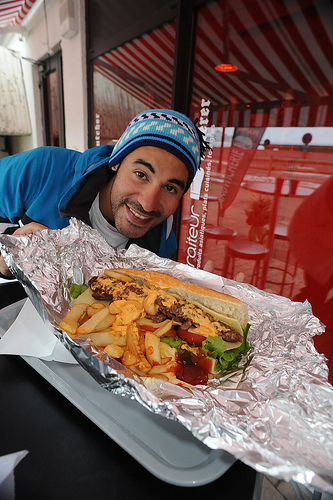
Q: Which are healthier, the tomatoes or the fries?
A: The tomatoes are healthier than the fries.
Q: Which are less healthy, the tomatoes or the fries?
A: The fries are less healthy than the tomatoes.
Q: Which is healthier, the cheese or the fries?
A: The cheese is healthier than the fries.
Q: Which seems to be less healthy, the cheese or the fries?
A: The fries is less healthy than the cheese.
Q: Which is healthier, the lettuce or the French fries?
A: The lettuce is healthier than the French fries.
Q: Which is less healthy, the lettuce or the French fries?
A: The French fries is less healthy than the lettuce.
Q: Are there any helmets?
A: No, there are no helmets.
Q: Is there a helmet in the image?
A: No, there are no helmets.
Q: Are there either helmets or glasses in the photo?
A: No, there are no helmets or glasses.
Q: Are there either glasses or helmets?
A: No, there are no helmets or glasses.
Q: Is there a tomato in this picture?
A: Yes, there are tomatoes.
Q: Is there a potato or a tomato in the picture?
A: Yes, there are tomatoes.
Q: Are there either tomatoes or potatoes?
A: Yes, there are tomatoes.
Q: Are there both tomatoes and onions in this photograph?
A: No, there are tomatoes but no onions.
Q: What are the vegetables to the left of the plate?
A: The vegetables are tomatoes.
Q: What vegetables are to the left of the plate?
A: The vegetables are tomatoes.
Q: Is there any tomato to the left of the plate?
A: Yes, there are tomatoes to the left of the plate.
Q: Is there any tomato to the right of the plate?
A: No, the tomatoes are to the left of the plate.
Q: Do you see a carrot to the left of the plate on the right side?
A: No, there are tomatoes to the left of the plate.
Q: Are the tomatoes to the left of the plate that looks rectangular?
A: Yes, the tomatoes are to the left of the plate.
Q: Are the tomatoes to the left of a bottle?
A: No, the tomatoes are to the left of the plate.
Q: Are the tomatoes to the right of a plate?
A: No, the tomatoes are to the left of a plate.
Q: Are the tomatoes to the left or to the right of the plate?
A: The tomatoes are to the left of the plate.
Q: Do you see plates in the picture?
A: Yes, there is a plate.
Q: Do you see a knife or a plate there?
A: Yes, there is a plate.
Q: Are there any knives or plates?
A: Yes, there is a plate.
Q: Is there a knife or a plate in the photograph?
A: Yes, there is a plate.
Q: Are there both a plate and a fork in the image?
A: No, there is a plate but no forks.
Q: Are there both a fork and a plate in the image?
A: No, there is a plate but no forks.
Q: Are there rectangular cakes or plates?
A: Yes, there is a rectangular plate.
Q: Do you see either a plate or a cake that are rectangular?
A: Yes, the plate is rectangular.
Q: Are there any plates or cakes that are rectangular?
A: Yes, the plate is rectangular.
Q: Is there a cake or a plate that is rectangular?
A: Yes, the plate is rectangular.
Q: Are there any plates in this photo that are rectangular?
A: Yes, there is a rectangular plate.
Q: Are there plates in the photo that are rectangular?
A: Yes, there is a plate that is rectangular.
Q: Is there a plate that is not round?
A: Yes, there is a rectangular plate.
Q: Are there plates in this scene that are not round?
A: Yes, there is a rectangular plate.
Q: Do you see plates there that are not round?
A: Yes, there is a rectangular plate.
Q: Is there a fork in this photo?
A: No, there are no forks.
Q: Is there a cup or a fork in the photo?
A: No, there are no forks or cups.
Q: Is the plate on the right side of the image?
A: Yes, the plate is on the right of the image.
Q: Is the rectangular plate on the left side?
A: No, the plate is on the right of the image.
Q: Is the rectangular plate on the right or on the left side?
A: The plate is on the right of the image.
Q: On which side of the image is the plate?
A: The plate is on the right of the image.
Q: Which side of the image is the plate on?
A: The plate is on the right of the image.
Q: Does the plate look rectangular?
A: Yes, the plate is rectangular.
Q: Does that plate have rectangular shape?
A: Yes, the plate is rectangular.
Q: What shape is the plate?
A: The plate is rectangular.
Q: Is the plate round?
A: No, the plate is rectangular.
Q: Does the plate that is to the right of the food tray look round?
A: No, the plate is rectangular.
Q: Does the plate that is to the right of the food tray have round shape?
A: No, the plate is rectangular.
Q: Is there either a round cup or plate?
A: No, there is a plate but it is rectangular.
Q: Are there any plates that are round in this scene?
A: No, there is a plate but it is rectangular.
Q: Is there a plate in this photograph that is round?
A: No, there is a plate but it is rectangular.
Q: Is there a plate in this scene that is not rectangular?
A: No, there is a plate but it is rectangular.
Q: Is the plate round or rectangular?
A: The plate is rectangular.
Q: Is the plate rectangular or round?
A: The plate is rectangular.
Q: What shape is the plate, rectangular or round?
A: The plate is rectangular.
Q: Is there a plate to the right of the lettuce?
A: Yes, there is a plate to the right of the lettuce.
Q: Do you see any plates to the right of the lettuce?
A: Yes, there is a plate to the right of the lettuce.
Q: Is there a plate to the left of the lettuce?
A: No, the plate is to the right of the lettuce.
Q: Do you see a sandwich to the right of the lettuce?
A: No, there is a plate to the right of the lettuce.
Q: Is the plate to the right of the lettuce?
A: Yes, the plate is to the right of the lettuce.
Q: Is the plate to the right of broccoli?
A: No, the plate is to the right of the lettuce.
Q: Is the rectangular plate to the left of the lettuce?
A: No, the plate is to the right of the lettuce.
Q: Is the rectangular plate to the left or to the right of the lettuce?
A: The plate is to the right of the lettuce.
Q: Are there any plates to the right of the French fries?
A: Yes, there is a plate to the right of the French fries.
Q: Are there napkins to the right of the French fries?
A: No, there is a plate to the right of the French fries.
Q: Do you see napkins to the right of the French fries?
A: No, there is a plate to the right of the French fries.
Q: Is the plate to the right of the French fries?
A: Yes, the plate is to the right of the French fries.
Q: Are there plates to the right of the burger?
A: Yes, there is a plate to the right of the burger.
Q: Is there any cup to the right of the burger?
A: No, there is a plate to the right of the burger.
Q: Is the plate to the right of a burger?
A: Yes, the plate is to the right of a burger.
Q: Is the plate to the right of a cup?
A: No, the plate is to the right of a burger.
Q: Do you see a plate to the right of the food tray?
A: Yes, there is a plate to the right of the food tray.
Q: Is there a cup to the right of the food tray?
A: No, there is a plate to the right of the food tray.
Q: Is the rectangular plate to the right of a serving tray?
A: Yes, the plate is to the right of a serving tray.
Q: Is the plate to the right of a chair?
A: No, the plate is to the right of a serving tray.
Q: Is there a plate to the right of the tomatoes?
A: Yes, there is a plate to the right of the tomatoes.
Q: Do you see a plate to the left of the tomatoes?
A: No, the plate is to the right of the tomatoes.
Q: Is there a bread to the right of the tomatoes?
A: No, there is a plate to the right of the tomatoes.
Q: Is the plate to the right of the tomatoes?
A: Yes, the plate is to the right of the tomatoes.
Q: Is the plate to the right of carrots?
A: No, the plate is to the right of the tomatoes.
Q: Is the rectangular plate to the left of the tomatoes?
A: No, the plate is to the right of the tomatoes.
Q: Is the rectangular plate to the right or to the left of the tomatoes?
A: The plate is to the right of the tomatoes.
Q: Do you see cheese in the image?
A: Yes, there is cheese.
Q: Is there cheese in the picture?
A: Yes, there is cheese.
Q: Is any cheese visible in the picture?
A: Yes, there is cheese.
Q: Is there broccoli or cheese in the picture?
A: Yes, there is cheese.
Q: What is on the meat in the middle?
A: The cheese is on the meat.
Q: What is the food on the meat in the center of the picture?
A: The food is cheese.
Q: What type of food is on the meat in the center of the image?
A: The food is cheese.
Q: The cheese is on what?
A: The cheese is on the meat.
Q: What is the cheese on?
A: The cheese is on the meat.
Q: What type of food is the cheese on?
A: The cheese is on the meat.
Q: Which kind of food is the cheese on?
A: The cheese is on the meat.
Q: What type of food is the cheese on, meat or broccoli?
A: The cheese is on meat.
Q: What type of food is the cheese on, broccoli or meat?
A: The cheese is on meat.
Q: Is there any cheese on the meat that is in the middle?
A: Yes, there is cheese on the meat.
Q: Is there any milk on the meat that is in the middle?
A: No, there is cheese on the meat.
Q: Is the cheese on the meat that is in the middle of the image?
A: Yes, the cheese is on the meat.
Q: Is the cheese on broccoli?
A: No, the cheese is on the meat.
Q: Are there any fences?
A: No, there are no fences.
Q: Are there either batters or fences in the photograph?
A: No, there are no fences or batters.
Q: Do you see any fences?
A: No, there are no fences.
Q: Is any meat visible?
A: Yes, there is meat.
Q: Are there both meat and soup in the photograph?
A: No, there is meat but no soup.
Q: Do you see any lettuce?
A: Yes, there is lettuce.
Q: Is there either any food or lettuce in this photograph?
A: Yes, there is lettuce.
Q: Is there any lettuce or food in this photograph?
A: Yes, there is lettuce.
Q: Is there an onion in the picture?
A: No, there are no onions.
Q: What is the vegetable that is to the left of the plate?
A: The vegetable is lettuce.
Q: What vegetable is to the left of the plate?
A: The vegetable is lettuce.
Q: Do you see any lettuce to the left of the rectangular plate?
A: Yes, there is lettuce to the left of the plate.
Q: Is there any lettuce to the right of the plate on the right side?
A: No, the lettuce is to the left of the plate.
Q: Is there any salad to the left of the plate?
A: No, there is lettuce to the left of the plate.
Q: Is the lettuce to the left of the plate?
A: Yes, the lettuce is to the left of the plate.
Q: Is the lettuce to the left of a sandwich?
A: No, the lettuce is to the left of the plate.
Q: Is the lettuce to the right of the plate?
A: No, the lettuce is to the left of the plate.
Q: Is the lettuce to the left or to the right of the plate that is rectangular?
A: The lettuce is to the left of the plate.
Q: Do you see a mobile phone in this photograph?
A: No, there are no cell phones.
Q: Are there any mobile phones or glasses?
A: No, there are no mobile phones or glasses.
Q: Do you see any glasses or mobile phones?
A: No, there are no mobile phones or glasses.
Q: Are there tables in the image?
A: Yes, there is a table.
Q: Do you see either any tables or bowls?
A: Yes, there is a table.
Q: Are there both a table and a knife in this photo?
A: No, there is a table but no knives.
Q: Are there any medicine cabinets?
A: No, there are no medicine cabinets.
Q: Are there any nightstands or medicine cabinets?
A: No, there are no medicine cabinets or nightstands.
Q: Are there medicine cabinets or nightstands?
A: No, there are no medicine cabinets or nightstands.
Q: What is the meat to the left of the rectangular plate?
A: The meat is a burger.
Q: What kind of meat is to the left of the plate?
A: The meat is a burger.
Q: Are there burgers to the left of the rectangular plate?
A: Yes, there is a burger to the left of the plate.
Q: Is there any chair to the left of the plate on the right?
A: No, there is a burger to the left of the plate.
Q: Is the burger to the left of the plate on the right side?
A: Yes, the burger is to the left of the plate.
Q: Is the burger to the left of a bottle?
A: No, the burger is to the left of the plate.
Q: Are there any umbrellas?
A: No, there are no umbrellas.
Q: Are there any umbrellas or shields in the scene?
A: No, there are no umbrellas or shields.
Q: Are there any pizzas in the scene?
A: No, there are no pizzas.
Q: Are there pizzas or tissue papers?
A: No, there are no pizzas or tissue papers.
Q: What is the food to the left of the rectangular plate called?
A: The food is fries.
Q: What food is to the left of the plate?
A: The food is fries.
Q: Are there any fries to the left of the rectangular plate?
A: Yes, there are fries to the left of the plate.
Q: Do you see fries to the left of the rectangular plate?
A: Yes, there are fries to the left of the plate.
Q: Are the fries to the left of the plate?
A: Yes, the fries are to the left of the plate.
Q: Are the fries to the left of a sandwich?
A: No, the fries are to the left of the plate.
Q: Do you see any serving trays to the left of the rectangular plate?
A: Yes, there is a serving tray to the left of the plate.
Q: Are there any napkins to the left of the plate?
A: No, there is a serving tray to the left of the plate.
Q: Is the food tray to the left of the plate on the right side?
A: Yes, the food tray is to the left of the plate.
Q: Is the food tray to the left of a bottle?
A: No, the food tray is to the left of the plate.